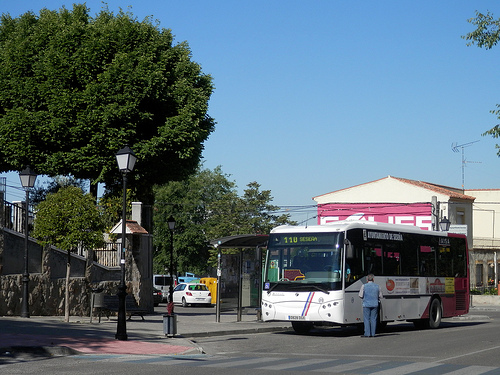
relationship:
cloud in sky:
[0, 0, 499, 226] [0, 3, 499, 232]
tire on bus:
[422, 295, 447, 329] [253, 210, 482, 337]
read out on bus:
[283, 234, 319, 243] [259, 218, 471, 333]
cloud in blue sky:
[0, 0, 499, 226] [216, 0, 499, 225]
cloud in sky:
[0, 0, 499, 226] [13, 2, 490, 214]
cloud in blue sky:
[0, 0, 499, 226] [2, 1, 499, 224]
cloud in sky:
[0, 0, 499, 226] [367, 52, 459, 151]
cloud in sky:
[0, 0, 499, 226] [207, 7, 471, 164]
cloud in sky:
[0, 0, 499, 226] [269, 31, 365, 99]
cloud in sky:
[0, 0, 499, 226] [193, 10, 493, 188]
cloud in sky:
[288, 168, 333, 189] [0, 3, 499, 232]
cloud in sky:
[0, 0, 499, 226] [249, 33, 499, 205]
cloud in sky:
[0, 0, 499, 226] [258, 23, 498, 188]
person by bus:
[355, 276, 386, 342] [253, 210, 482, 337]